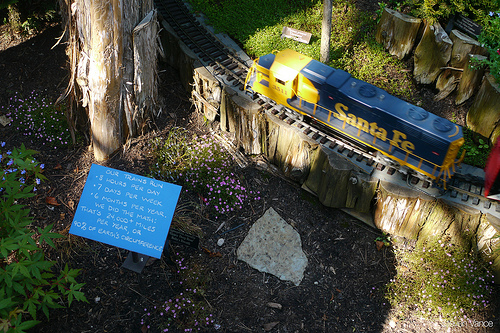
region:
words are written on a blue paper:
[80, 154, 168, 288]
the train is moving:
[223, 34, 498, 219]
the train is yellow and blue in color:
[247, 34, 476, 191]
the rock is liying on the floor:
[234, 217, 325, 286]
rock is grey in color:
[235, 207, 331, 306]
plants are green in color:
[6, 214, 80, 331]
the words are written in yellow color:
[324, 101, 421, 172]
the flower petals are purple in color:
[203, 166, 265, 237]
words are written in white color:
[78, 175, 158, 255]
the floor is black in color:
[318, 292, 361, 330]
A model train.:
[243, 46, 467, 189]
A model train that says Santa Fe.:
[247, 44, 467, 187]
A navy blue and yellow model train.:
[243, 43, 467, 185]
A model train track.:
[152, 0, 498, 221]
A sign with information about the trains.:
[67, 157, 183, 261]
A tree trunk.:
[61, 2, 169, 160]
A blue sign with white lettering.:
[70, 159, 184, 258]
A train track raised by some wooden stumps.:
[155, 1, 497, 269]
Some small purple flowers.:
[0, 92, 263, 332]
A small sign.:
[280, 24, 313, 46]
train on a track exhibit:
[253, 27, 466, 183]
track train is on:
[166, 15, 232, 69]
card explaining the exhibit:
[284, 21, 313, 46]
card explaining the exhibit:
[448, 9, 482, 41]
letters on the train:
[330, 100, 420, 155]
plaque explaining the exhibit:
[63, 160, 183, 263]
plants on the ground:
[6, 158, 75, 324]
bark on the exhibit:
[378, 4, 498, 114]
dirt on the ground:
[240, 252, 389, 325]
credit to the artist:
[418, 313, 498, 328]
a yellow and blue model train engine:
[242, 46, 465, 187]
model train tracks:
[156, 2, 498, 211]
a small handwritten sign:
[68, 161, 182, 274]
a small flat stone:
[235, 207, 307, 285]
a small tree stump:
[58, 0, 163, 156]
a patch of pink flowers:
[154, 132, 266, 217]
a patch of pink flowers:
[141, 258, 213, 332]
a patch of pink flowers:
[384, 233, 496, 317]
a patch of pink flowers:
[4, 85, 73, 151]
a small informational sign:
[282, 24, 312, 44]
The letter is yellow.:
[328, 98, 348, 128]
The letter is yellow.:
[344, 109, 357, 132]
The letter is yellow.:
[354, 111, 371, 138]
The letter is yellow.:
[364, 117, 379, 139]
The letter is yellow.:
[373, 125, 386, 146]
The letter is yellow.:
[383, 115, 405, 153]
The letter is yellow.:
[398, 140, 419, 159]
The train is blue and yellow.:
[236, 46, 471, 188]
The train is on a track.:
[169, 7, 484, 204]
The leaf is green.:
[62, 277, 99, 307]